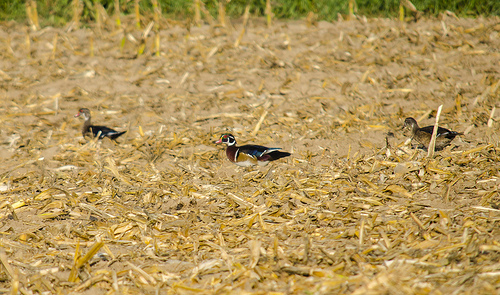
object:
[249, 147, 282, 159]
duck wing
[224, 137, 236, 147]
stripes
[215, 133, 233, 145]
head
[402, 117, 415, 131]
hace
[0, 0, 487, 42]
grass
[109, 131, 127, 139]
tail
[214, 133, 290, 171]
bird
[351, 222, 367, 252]
wood chips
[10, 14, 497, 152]
mulch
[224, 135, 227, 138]
redeye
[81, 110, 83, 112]
redeye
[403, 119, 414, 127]
duck face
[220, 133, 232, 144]
duck face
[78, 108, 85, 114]
duck face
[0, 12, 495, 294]
chips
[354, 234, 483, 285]
straw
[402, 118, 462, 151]
bird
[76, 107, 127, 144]
bird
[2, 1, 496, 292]
ground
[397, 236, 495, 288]
dried leaves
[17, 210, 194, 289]
dried leaves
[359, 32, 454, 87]
dried leaves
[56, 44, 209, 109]
dried leaves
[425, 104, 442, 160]
tan straw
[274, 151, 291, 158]
tail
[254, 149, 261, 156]
section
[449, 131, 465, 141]
tail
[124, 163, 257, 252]
straw